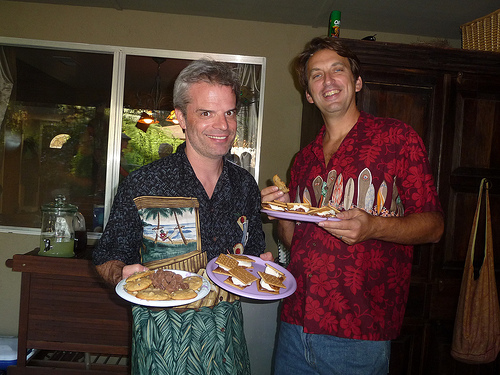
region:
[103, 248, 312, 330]
food for the men to eat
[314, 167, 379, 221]
surfboards on the red shirt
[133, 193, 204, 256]
beach scene on the blue shirt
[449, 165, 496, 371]
a handbag hanging on a knob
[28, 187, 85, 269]
lemonade in glass container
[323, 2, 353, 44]
a can of Off bug spray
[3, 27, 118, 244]
a window behind the men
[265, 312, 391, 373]
jeans on the man in red shirt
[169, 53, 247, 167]
a smiling happy face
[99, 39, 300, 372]
a man holding two dishes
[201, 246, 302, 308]
a purple paper dish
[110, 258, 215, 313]
a white dish with cookies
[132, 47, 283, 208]
man has gray hair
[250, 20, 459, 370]
man wearing a red shirt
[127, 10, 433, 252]
two happy smiling men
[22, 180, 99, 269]
a dispenser with lemonade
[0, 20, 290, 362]
a window on back a man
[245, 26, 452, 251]
a man holding a dish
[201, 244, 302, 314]
a dish with cookies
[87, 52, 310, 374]
a man holds two plates of food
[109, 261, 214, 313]
cookies on a white plate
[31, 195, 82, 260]
a glass drink dispenser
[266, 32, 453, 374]
a man wears a red shirt with surfboards on it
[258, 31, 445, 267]
man has half a cookie in his right hand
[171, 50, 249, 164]
man with grey hair is smiling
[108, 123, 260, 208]
people are gathered outside a window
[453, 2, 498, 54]
a woven basket is on top of a tall wooden cupboard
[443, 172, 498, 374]
a bag hangs on a wooden cupboard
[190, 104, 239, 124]
a pair of brown eyes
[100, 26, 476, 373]
two guys smiling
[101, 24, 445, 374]
two guys on vacation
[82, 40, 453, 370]
two guys holding food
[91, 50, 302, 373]
guy wearing a hawaiian style shirt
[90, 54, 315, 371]
guy holding two plates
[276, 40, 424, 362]
guy wearing a red shirt with flowers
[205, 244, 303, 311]
purple plate with s'mores on it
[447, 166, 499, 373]
big orange purse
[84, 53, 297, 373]
guy with grey hair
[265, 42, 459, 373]
guy with brown hair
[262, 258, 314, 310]
two smores on purple plate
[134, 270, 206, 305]
cookies on white plate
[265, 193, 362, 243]
plate full of smores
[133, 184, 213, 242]
green palm trees on shirt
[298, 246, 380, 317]
red floral button shirt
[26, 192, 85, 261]
glass container of lemonade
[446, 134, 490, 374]
light brown purse with straps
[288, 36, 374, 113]
brown hair on smiling man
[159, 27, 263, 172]
silver hair on smiling man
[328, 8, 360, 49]
off bug spray on furniture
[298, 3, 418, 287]
a man standing inside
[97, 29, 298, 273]
a window on the wall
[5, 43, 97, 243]
a window onthe wall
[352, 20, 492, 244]
a brown wooden chest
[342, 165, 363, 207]
surfboard on the shirt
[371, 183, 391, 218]
surfboard on the shirt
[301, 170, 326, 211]
surfboard on the shirt